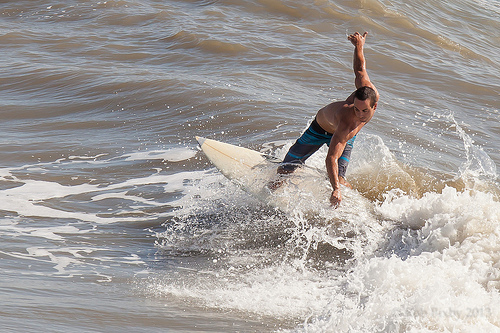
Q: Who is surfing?
A: The guy.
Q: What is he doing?
A: Surfing.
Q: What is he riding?
A: A wave.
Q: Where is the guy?
A: In the water.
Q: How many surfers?
A: 1.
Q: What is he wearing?
A: Shorts.